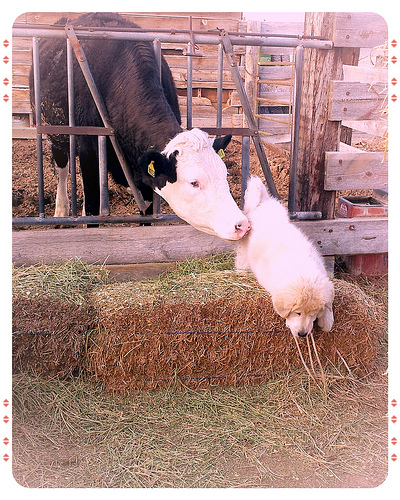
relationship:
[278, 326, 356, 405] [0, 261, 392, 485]
hay stick on field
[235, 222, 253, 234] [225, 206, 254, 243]
ring through nose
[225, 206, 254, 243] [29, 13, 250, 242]
nose of bull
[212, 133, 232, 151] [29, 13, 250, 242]
ear on bull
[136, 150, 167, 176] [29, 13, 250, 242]
ear on bull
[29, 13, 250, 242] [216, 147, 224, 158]
bull wearing tags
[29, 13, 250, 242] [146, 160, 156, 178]
bull wearing tags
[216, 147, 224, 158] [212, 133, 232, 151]
tags in ear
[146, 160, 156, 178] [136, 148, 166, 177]
tags in ear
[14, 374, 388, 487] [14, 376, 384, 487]
straw on ground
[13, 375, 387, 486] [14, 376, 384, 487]
grass on ground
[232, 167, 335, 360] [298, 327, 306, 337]
puppy has nose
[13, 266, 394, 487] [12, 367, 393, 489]
hay on field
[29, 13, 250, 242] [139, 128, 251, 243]
bull has head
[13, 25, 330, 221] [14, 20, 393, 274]
gate on fence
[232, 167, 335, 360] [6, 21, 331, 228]
puppy in front of metal pen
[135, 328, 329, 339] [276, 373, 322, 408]
rope around hay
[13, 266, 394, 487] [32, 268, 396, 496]
hay on field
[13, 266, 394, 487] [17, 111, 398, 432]
hay in field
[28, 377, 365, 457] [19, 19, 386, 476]
grain on field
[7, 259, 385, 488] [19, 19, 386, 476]
grain on field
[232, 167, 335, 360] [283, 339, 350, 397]
puppy playing with rope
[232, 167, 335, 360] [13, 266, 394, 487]
puppy standing on hay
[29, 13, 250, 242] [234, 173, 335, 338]
bull curious about puppy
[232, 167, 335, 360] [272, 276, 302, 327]
puppy has ears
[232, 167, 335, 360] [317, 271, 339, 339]
puppy has ears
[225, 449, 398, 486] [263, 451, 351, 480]
area of dirt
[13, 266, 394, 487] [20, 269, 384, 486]
hay on ground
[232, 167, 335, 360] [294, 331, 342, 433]
puppy has rope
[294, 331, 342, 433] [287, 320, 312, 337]
rope in mouth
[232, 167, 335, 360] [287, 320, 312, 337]
puppy has mouth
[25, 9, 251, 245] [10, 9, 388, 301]
cow inside gate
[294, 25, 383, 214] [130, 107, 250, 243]
fence next to cow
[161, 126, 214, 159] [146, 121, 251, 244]
hair on head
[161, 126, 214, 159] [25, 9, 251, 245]
hair on cow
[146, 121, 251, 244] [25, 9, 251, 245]
head on cow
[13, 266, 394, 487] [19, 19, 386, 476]
hay on field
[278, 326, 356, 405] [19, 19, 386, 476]
hay stick on field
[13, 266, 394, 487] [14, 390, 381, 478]
hay on field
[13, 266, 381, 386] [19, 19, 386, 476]
hay on field